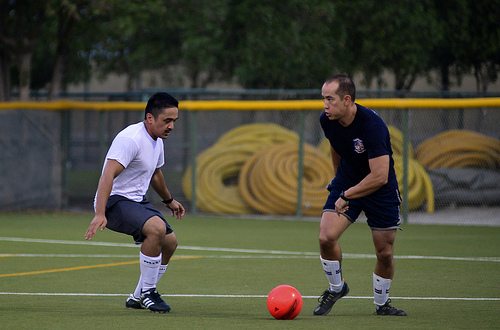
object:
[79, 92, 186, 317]
players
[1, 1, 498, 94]
tree tops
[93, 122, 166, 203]
white shirt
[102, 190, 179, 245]
gray shorts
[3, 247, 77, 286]
lines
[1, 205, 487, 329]
field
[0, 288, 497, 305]
lines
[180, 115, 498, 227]
yellow hoses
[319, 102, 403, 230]
navy uniform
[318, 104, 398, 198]
blue shirt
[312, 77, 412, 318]
player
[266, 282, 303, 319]
ball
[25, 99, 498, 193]
green fencing